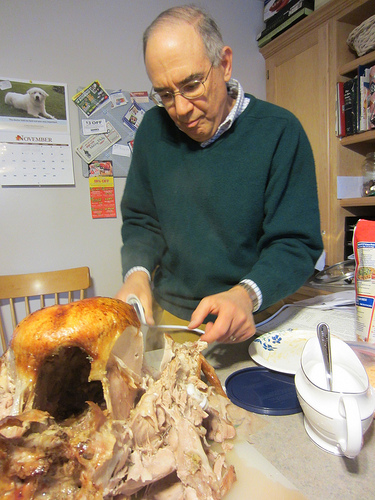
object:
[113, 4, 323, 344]
man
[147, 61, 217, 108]
glasses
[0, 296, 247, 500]
turkey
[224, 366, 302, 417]
lid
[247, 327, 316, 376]
saucer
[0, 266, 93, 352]
chair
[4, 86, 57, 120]
dog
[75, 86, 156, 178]
board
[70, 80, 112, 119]
post card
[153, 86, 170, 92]
eyebrow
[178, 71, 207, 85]
eyebrow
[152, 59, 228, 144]
face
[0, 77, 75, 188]
poster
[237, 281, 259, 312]
watch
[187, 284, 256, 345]
hand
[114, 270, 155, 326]
hand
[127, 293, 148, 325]
carving knife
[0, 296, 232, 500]
platter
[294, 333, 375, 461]
gravy bowl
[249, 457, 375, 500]
table top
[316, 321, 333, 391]
utensil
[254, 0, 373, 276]
cabinet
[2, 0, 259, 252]
wall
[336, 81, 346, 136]
book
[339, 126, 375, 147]
shelf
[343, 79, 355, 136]
book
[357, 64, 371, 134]
book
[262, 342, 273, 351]
flower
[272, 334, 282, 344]
flower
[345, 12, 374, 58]
basket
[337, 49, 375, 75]
top shelf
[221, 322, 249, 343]
finger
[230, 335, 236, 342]
ring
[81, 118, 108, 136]
coupon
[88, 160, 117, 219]
coupon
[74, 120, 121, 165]
coupon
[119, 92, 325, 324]
sweater